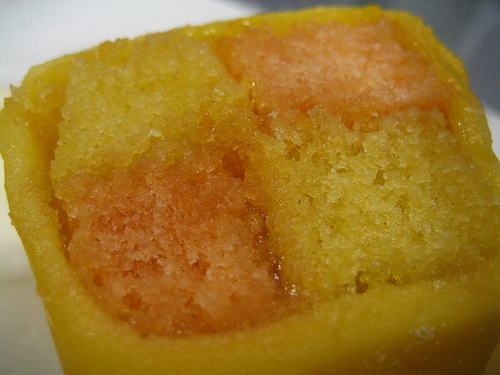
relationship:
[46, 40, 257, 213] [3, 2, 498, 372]
cake of food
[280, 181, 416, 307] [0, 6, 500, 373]
part of yellow food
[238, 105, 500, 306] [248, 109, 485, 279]
part of yellow food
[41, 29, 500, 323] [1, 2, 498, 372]
sheep on cake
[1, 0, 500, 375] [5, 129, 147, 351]
cake on border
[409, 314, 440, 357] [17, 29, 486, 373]
white substance on cake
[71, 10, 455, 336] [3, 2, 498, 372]
orange squares on food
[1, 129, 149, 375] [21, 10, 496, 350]
border on corn bread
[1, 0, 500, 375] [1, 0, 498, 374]
cake on table